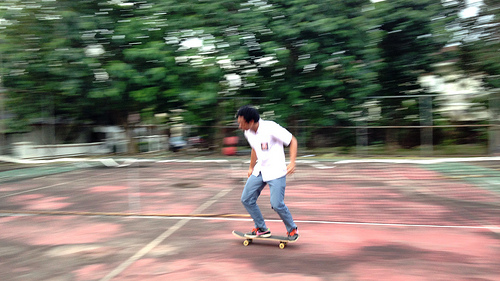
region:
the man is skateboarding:
[220, 70, 306, 261]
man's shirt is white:
[245, 121, 300, 176]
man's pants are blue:
[226, 165, 302, 221]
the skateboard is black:
[235, 220, 320, 270]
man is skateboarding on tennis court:
[222, 90, 334, 270]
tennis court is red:
[15, 135, 475, 271]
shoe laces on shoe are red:
[250, 225, 305, 245]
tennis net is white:
[5, 140, 475, 235]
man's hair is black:
[236, 105, 258, 125]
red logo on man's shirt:
[255, 136, 275, 157]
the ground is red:
[109, 193, 227, 272]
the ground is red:
[79, 134, 212, 276]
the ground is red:
[56, 187, 141, 263]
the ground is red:
[189, 221, 241, 278]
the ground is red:
[159, 190, 211, 277]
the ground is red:
[140, 172, 182, 267]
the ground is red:
[88, 189, 168, 265]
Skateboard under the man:
[231, 227, 303, 248]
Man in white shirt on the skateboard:
[225, 103, 303, 233]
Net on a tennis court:
[9, 155, 201, 212]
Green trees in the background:
[8, 7, 432, 84]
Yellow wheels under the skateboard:
[240, 240, 290, 251]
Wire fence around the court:
[365, 92, 499, 152]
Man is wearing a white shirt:
[238, 124, 298, 176]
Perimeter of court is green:
[414, 143, 498, 190]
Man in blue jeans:
[237, 175, 297, 226]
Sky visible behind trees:
[175, 24, 235, 79]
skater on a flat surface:
[222, 96, 310, 253]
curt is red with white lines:
[5, 144, 498, 279]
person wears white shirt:
[225, 99, 310, 249]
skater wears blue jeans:
[225, 106, 310, 250]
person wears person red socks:
[243, 214, 302, 241]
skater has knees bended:
[220, 176, 312, 226]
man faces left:
[217, 96, 315, 251]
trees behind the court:
[6, 5, 496, 110]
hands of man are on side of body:
[224, 97, 305, 185]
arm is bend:
[268, 120, 305, 178]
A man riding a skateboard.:
[218, 100, 305, 253]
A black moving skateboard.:
[234, 227, 303, 248]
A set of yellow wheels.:
[236, 237, 291, 249]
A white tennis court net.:
[7, 151, 498, 229]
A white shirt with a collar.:
[238, 119, 305, 185]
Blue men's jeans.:
[229, 165, 303, 227]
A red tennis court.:
[21, 155, 493, 279]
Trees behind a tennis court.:
[3, 4, 491, 114]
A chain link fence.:
[275, 94, 497, 153]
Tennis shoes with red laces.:
[239, 223, 300, 241]